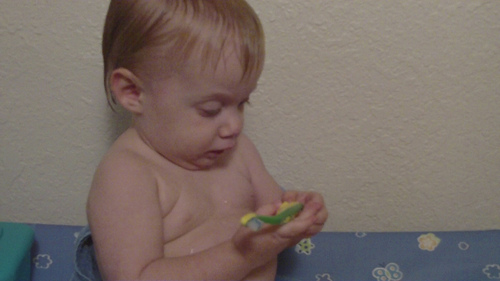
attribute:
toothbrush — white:
[238, 199, 309, 227]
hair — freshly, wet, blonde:
[103, 0, 267, 83]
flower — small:
[414, 232, 440, 253]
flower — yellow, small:
[480, 264, 498, 276]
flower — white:
[291, 237, 314, 256]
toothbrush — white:
[194, 177, 324, 245]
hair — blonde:
[62, 15, 292, 83]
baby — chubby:
[80, 0, 310, 277]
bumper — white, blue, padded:
[28, 222, 495, 278]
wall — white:
[1, 0, 498, 220]